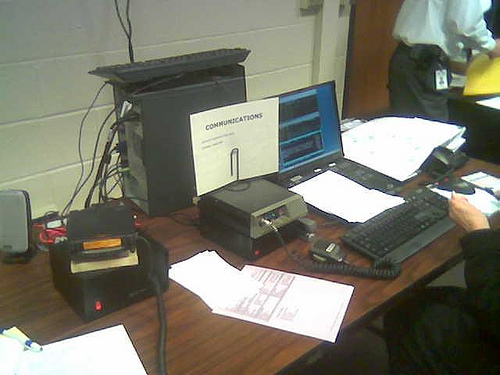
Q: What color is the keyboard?
A: Black.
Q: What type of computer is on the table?
A: Laptop.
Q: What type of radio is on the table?
A: CB radio.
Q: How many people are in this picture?
A: 2.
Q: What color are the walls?
A: White.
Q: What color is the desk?
A: Brown.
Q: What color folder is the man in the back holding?
A: Yellow.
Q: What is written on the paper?
A: Communications.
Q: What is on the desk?
A: Papers.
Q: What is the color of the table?
A: Brown.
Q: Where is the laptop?
A: On the table.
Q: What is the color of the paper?
A: White.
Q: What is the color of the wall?
A: White.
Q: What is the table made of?
A: Wood.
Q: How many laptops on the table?
A: One.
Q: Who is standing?
A: The man.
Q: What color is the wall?
A: White.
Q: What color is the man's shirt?
A: White.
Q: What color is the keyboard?
A: Black.